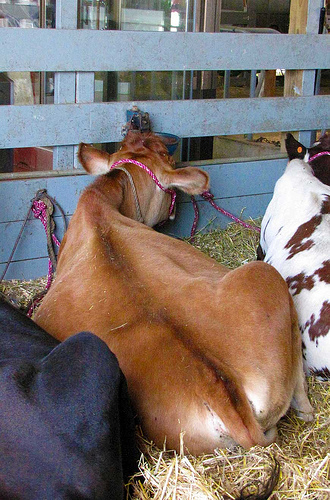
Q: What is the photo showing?
A: It is showing a pen.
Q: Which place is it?
A: It is a pen.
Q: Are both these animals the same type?
A: Yes, all the animals are cows.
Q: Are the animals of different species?
A: No, all the animals are cows.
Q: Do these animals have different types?
A: No, all the animals are cows.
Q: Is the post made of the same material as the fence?
A: Yes, both the post and the fence are made of wood.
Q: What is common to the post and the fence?
A: The material, both the post and the fence are wooden.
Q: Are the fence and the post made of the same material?
A: Yes, both the fence and the post are made of wood.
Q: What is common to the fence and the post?
A: The material, both the fence and the post are wooden.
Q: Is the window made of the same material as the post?
A: No, the window is made of glass and the post is made of wood.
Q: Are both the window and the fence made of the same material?
A: No, the window is made of glass and the fence is made of wood.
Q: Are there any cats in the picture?
A: No, there are no cats.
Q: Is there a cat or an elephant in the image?
A: No, there are no cats or elephants.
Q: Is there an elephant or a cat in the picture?
A: No, there are no cats or elephants.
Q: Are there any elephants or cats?
A: No, there are no cats or elephants.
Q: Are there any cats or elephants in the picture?
A: No, there are no cats or elephants.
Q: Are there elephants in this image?
A: No, there are no elephants.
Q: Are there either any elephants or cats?
A: No, there are no elephants or cats.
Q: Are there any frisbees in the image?
A: No, there are no frisbees.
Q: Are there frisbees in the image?
A: No, there are no frisbees.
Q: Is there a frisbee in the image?
A: No, there are no frisbees.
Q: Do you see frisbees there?
A: No, there are no frisbees.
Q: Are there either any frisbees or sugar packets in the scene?
A: No, there are no frisbees or sugar packets.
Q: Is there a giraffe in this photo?
A: No, there are no giraffes.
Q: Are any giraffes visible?
A: No, there are no giraffes.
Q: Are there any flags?
A: No, there are no flags.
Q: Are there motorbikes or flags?
A: No, there are no flags or motorbikes.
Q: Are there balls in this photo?
A: No, there are no balls.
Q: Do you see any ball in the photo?
A: No, there are no balls.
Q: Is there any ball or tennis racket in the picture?
A: No, there are no balls or rackets.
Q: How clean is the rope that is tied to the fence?
A: The rope is dirty.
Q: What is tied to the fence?
A: The rope is tied to the fence.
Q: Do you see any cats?
A: No, there are no cats.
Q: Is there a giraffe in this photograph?
A: No, there are no giraffes.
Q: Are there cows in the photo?
A: Yes, there is a cow.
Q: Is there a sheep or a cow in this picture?
A: Yes, there is a cow.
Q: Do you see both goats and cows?
A: No, there is a cow but no goats.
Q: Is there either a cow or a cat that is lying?
A: Yes, the cow is lying.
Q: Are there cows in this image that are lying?
A: Yes, there is a cow that is lying.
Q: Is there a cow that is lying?
A: Yes, there is a cow that is lying.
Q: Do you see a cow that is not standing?
A: Yes, there is a cow that is lying .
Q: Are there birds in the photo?
A: No, there are no birds.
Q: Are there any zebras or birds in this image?
A: No, there are no birds or zebras.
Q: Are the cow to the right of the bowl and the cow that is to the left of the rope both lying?
A: Yes, both the cow and the cow are lying.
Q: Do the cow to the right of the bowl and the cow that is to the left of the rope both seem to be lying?
A: Yes, both the cow and the cow are lying.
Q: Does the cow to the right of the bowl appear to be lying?
A: Yes, the cow is lying.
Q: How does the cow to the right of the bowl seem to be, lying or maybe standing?
A: The cow is lying.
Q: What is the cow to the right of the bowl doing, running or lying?
A: The cow is lying.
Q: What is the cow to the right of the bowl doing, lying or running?
A: The cow is lying.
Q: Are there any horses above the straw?
A: No, there is a cow above the straw.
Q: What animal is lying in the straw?
A: The cow is lying in the straw.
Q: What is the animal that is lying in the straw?
A: The animal is a cow.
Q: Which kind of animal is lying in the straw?
A: The animal is a cow.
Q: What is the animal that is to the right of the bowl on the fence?
A: The animal is a cow.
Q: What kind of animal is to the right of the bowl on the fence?
A: The animal is a cow.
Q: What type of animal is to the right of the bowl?
A: The animal is a cow.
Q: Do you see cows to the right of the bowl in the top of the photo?
A: Yes, there is a cow to the right of the bowl.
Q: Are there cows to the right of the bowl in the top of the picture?
A: Yes, there is a cow to the right of the bowl.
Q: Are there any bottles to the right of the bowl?
A: No, there is a cow to the right of the bowl.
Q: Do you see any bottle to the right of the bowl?
A: No, there is a cow to the right of the bowl.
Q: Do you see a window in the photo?
A: Yes, there is a window.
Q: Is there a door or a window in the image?
A: Yes, there is a window.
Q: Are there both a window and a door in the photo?
A: No, there is a window but no doors.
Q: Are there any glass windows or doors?
A: Yes, there is a glass window.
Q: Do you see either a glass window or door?
A: Yes, there is a glass window.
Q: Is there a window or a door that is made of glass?
A: Yes, the window is made of glass.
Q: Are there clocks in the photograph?
A: No, there are no clocks.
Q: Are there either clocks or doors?
A: No, there are no clocks or doors.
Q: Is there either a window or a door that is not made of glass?
A: No, there is a window but it is made of glass.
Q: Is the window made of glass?
A: Yes, the window is made of glass.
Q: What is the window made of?
A: The window is made of glass.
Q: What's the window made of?
A: The window is made of glass.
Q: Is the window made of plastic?
A: No, the window is made of glass.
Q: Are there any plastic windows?
A: No, there is a window but it is made of glass.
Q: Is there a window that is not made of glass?
A: No, there is a window but it is made of glass.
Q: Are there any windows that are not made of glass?
A: No, there is a window but it is made of glass.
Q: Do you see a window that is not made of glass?
A: No, there is a window but it is made of glass.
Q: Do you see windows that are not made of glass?
A: No, there is a window but it is made of glass.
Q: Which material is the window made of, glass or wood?
A: The window is made of glass.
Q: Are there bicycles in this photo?
A: No, there are no bicycles.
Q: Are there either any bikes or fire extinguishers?
A: No, there are no bikes or fire extinguishers.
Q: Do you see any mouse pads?
A: No, there are no mouse pads.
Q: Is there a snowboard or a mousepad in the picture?
A: No, there are no mouse pads or snowboards.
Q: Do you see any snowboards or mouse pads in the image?
A: No, there are no mouse pads or snowboards.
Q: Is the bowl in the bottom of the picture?
A: No, the bowl is in the top of the image.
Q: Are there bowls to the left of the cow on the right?
A: Yes, there is a bowl to the left of the cow.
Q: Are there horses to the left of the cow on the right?
A: No, there is a bowl to the left of the cow.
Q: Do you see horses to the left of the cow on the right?
A: No, there is a bowl to the left of the cow.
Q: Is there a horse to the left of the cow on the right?
A: No, there is a bowl to the left of the cow.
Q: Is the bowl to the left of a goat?
A: No, the bowl is to the left of the cow.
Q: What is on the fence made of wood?
A: The bowl is on the fence.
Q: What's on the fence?
A: The bowl is on the fence.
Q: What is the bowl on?
A: The bowl is on the fence.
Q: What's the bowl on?
A: The bowl is on the fence.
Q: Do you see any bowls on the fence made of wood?
A: Yes, there is a bowl on the fence.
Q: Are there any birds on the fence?
A: No, there is a bowl on the fence.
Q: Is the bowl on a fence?
A: Yes, the bowl is on a fence.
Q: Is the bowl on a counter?
A: No, the bowl is on a fence.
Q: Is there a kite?
A: No, there are no kites.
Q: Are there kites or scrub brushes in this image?
A: No, there are no kites or scrub brushes.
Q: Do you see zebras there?
A: No, there are no zebras.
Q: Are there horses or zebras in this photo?
A: No, there are no zebras or horses.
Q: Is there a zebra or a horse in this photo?
A: No, there are no zebras or horses.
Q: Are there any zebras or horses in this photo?
A: No, there are no zebras or horses.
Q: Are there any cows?
A: Yes, there is a cow.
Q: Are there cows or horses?
A: Yes, there is a cow.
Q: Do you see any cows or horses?
A: Yes, there is a cow.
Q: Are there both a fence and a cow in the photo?
A: Yes, there are both a cow and a fence.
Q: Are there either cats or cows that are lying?
A: Yes, the cow is lying.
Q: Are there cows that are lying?
A: Yes, there is a cow that is lying.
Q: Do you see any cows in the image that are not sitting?
A: Yes, there is a cow that is lying .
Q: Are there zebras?
A: No, there are no zebras.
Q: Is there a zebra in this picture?
A: No, there are no zebras.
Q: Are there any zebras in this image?
A: No, there are no zebras.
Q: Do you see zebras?
A: No, there are no zebras.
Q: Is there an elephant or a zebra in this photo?
A: No, there are no zebras or elephants.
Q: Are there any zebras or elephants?
A: No, there are no zebras or elephants.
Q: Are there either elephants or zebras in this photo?
A: No, there are no zebras or elephants.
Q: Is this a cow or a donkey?
A: This is a cow.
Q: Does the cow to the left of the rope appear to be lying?
A: Yes, the cow is lying.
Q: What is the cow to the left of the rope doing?
A: The cow is lying.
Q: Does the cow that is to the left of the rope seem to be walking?
A: No, the cow is lying.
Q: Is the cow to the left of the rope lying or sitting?
A: The cow is lying.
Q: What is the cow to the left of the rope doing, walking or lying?
A: The cow is lying.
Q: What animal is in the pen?
A: The cow is in the pen.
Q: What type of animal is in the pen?
A: The animal is a cow.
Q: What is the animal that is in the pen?
A: The animal is a cow.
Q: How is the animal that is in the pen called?
A: The animal is a cow.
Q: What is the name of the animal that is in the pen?
A: The animal is a cow.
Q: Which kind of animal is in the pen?
A: The animal is a cow.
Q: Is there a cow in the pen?
A: Yes, there is a cow in the pen.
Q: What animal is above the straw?
A: The animal is a cow.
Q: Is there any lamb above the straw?
A: No, there is a cow above the straw.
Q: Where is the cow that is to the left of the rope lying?
A: The cow is lying in the straw.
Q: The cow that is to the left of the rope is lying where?
A: The cow is lying in the straw.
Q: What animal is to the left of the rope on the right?
A: The animal is a cow.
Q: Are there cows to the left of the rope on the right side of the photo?
A: Yes, there is a cow to the left of the rope.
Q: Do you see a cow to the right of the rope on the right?
A: No, the cow is to the left of the rope.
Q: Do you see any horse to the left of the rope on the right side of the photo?
A: No, there is a cow to the left of the rope.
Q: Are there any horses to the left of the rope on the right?
A: No, there is a cow to the left of the rope.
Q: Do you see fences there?
A: Yes, there is a fence.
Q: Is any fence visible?
A: Yes, there is a fence.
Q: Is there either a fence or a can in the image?
A: Yes, there is a fence.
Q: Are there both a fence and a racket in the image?
A: No, there is a fence but no rackets.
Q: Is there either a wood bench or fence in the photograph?
A: Yes, there is a wood fence.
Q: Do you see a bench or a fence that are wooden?
A: Yes, the fence is wooden.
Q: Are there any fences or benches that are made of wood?
A: Yes, the fence is made of wood.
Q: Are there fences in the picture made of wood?
A: Yes, there is a fence that is made of wood.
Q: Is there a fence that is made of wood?
A: Yes, there is a fence that is made of wood.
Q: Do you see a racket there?
A: No, there are no rackets.